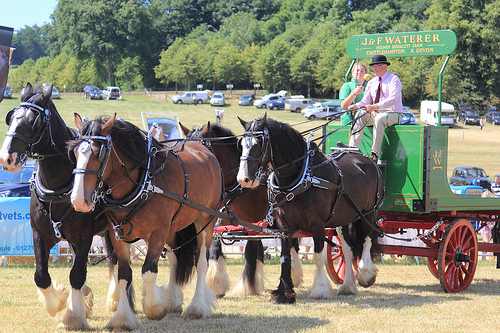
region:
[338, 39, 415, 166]
this is a person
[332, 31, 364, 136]
this is a person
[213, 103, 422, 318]
this is a horse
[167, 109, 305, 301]
this is a horse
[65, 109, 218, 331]
this is a horse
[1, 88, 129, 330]
this is a horse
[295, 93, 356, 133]
this is a car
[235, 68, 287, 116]
this is a car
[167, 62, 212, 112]
this is a car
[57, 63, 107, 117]
this is a car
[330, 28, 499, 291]
part of a green and red carriage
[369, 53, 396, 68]
a man's black hat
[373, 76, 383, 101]
a red tie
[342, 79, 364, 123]
part of a woman's green shirt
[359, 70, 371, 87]
a microphone with a yellow top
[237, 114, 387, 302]
a brown and white horse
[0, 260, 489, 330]
a section of green and brown grass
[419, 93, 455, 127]
a white camper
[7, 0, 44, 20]
part of a blue sky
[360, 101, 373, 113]
the hand of a man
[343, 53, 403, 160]
A man driving a team of horses.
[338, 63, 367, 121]
A person wearing a green shirt.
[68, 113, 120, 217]
The head of a light brown horse.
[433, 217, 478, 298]
The front left wheel of the wagon.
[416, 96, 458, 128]
A camper parked in the parking lot.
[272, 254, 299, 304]
A brown hoof of a horse.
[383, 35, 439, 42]
The last name of Waterer.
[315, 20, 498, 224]
A green wagon pulled by a team of horses.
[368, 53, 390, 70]
A black hat worn by a man.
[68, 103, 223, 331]
A light brown horse in front of the team.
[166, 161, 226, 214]
a brown horse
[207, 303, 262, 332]
shadow on the ground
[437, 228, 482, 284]
frong wheel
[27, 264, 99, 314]
the horses legs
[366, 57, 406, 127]
a person sitting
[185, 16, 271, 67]
the green leaves on the trees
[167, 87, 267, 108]
cars in the field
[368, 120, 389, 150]
man wearing pants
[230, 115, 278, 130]
the horses ears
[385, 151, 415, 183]
the shadow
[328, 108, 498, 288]
a green wagon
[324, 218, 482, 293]
rd wheels on wagon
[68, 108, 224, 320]
a light brown horse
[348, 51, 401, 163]
a man on the wagon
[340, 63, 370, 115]
a man holding a mic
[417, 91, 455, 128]
a campus on field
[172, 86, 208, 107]
a van on field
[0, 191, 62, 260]
a banner on the side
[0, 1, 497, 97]
trees along side of field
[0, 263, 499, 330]
the dead grass